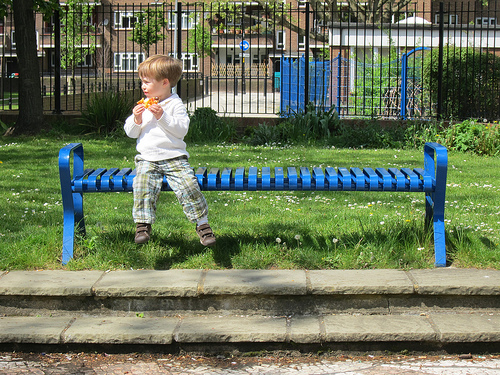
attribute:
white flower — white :
[294, 233, 300, 239]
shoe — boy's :
[194, 214, 221, 248]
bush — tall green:
[406, 36, 498, 161]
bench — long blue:
[55, 135, 449, 270]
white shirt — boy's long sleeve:
[124, 92, 196, 159]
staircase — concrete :
[2, 265, 497, 373]